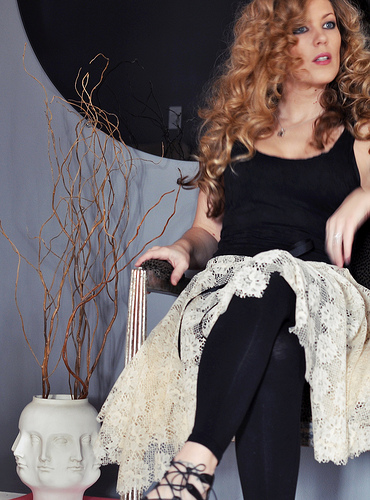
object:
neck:
[257, 76, 330, 148]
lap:
[187, 247, 368, 355]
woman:
[134, 21, 368, 498]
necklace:
[273, 112, 321, 138]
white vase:
[6, 389, 104, 498]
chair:
[124, 251, 191, 362]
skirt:
[146, 234, 370, 453]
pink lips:
[312, 50, 333, 67]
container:
[5, 388, 109, 500]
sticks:
[2, 41, 181, 399]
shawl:
[94, 246, 369, 499]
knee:
[227, 267, 295, 328]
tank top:
[200, 103, 364, 267]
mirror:
[15, 0, 247, 164]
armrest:
[120, 253, 187, 360]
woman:
[221, 128, 360, 258]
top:
[140, 2, 360, 496]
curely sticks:
[27, 76, 108, 395]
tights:
[181, 265, 315, 498]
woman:
[146, 4, 369, 302]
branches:
[24, 44, 200, 405]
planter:
[10, 393, 104, 498]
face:
[44, 415, 105, 488]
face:
[25, 402, 73, 495]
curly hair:
[175, 0, 369, 225]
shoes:
[147, 461, 218, 497]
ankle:
[168, 436, 217, 497]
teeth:
[316, 55, 330, 63]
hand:
[133, 239, 190, 285]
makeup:
[290, 18, 317, 38]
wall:
[4, 2, 358, 497]